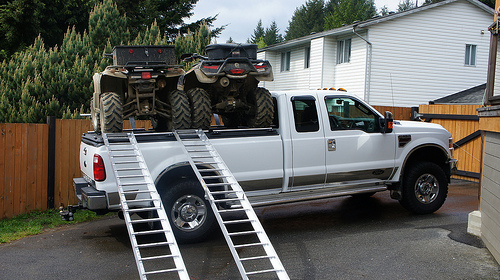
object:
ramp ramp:
[101, 129, 289, 279]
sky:
[180, 0, 425, 47]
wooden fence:
[3, 119, 153, 217]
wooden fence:
[368, 104, 497, 183]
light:
[93, 154, 106, 182]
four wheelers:
[90, 43, 276, 135]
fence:
[412, 103, 480, 182]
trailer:
[49, 83, 470, 228]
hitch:
[55, 190, 101, 240]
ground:
[410, 70, 455, 107]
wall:
[371, 1, 488, 102]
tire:
[398, 159, 450, 214]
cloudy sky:
[176, 0, 425, 42]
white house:
[259, 0, 499, 105]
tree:
[26, 31, 103, 106]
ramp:
[168, 129, 292, 279]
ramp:
[100, 129, 190, 278]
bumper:
[73, 176, 106, 208]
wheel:
[414, 173, 438, 205]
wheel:
[170, 195, 208, 232]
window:
[281, 52, 290, 72]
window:
[463, 43, 476, 68]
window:
[335, 38, 351, 65]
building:
[251, 0, 500, 120]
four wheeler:
[87, 44, 191, 138]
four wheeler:
[182, 40, 274, 130]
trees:
[3, 27, 93, 118]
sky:
[197, 0, 279, 42]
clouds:
[195, 0, 274, 31]